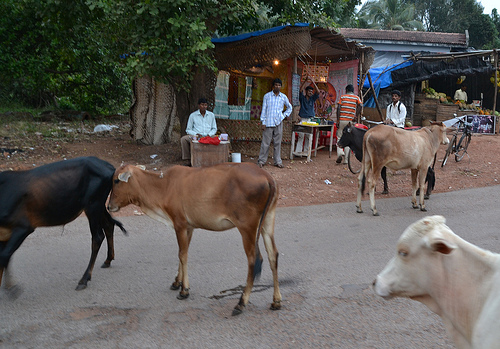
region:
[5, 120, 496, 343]
cows on the road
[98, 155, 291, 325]
brown cow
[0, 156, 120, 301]
black cow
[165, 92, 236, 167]
man sitting behind desk-like object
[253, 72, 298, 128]
man wearing a blue and white shirt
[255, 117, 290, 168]
man wearing grey pants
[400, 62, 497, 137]
man standing behind a stand containing fruit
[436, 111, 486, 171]
bicycle on the dirt ground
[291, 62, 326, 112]
person with their arms raised above their head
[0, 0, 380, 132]
trees behind enclosed area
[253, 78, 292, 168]
Man standing watching the cattle.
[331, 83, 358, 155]
Man in orange striped shirt and khaki pants.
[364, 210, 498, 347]
Tan/beige colored cattle.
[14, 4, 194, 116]
Trees and shrubs behind the open air stand.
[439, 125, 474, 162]
Man's bicycle parked on dirt.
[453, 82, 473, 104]
Man selling vegetables.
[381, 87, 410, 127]
Younger man with white shirt and grey hat.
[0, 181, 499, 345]
Paved roadway.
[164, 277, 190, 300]
Two front hooves of light brown cattle.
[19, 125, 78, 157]
Garbage/trash on ground.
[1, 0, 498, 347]
several young, holy animals before several stands in india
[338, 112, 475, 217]
2 bovine near 2 bicycle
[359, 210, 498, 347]
various cream colored cow sans horns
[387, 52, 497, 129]
produce stand in the right hand middle distance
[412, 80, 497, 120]
indeterminate orange, yellow, green produce @ produce stand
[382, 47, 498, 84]
a black fabric tarp covers produce stand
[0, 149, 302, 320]
an adolescent indian brown cow bumps the butt end of a darker brown adolescent indian cow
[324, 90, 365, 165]
orange+black+off-white stripe western-type shirt worn with light color western-type khakis [unlike kerouac's, say]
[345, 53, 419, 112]
bright blue plastic tarp besides black tarp covering produce stand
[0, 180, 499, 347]
a neatly kept gravel road trod by cows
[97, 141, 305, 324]
Brown cow in the road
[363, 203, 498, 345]
White cow facing left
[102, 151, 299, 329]
Brown cow pushing a black cow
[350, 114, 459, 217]
Brown cow facing right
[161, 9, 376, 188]
Small outdoor store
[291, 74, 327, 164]
People behind a table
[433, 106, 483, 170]
Bike park on side of road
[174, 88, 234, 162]
Man sitting in front a box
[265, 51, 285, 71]
Light in the store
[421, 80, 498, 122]
Person selling fruits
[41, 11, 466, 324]
animals on road near people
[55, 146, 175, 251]
calf head touching rear of another animal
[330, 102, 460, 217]
two animals headed in different directions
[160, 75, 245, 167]
man seated at wooden table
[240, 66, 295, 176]
man standing with a bent arm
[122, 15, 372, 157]
blue roof creating patio in front of building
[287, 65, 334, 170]
man behind table with arms raised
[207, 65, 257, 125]
window opening surrounded by blue and white material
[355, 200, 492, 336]
white cow with staring eye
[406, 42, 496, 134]
man selling produce at stand